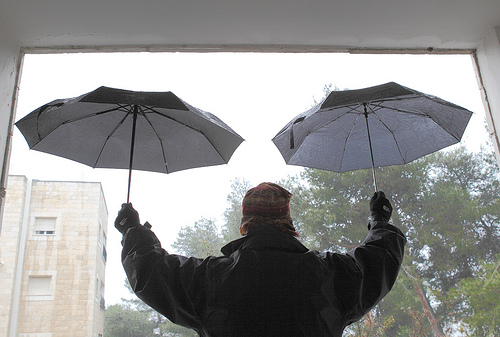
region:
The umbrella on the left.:
[20, 89, 241, 167]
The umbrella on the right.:
[274, 72, 478, 178]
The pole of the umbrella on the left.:
[124, 110, 139, 202]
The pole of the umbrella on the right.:
[362, 107, 384, 188]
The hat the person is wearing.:
[240, 182, 293, 219]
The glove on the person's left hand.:
[111, 198, 137, 230]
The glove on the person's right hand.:
[366, 190, 390, 220]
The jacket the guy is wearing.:
[127, 231, 404, 335]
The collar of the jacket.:
[215, 233, 309, 255]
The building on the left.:
[5, 170, 114, 334]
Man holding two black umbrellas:
[113, 176, 407, 335]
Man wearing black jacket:
[112, 180, 406, 335]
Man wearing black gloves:
[112, 180, 407, 335]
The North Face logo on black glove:
[117, 214, 130, 228]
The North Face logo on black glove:
[380, 200, 392, 212]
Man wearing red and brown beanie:
[112, 177, 407, 335]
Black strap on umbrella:
[285, 115, 305, 151]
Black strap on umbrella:
[32, 100, 66, 147]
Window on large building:
[34, 213, 58, 234]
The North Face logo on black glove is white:
[115, 213, 128, 227]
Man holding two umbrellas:
[12, 78, 477, 335]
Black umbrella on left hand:
[13, 86, 248, 261]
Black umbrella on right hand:
[271, 77, 480, 249]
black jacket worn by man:
[112, 223, 411, 335]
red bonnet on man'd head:
[238, 180, 296, 220]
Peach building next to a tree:
[0, 177, 112, 335]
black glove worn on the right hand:
[367, 190, 397, 228]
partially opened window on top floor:
[27, 209, 64, 238]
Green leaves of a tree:
[443, 265, 498, 330]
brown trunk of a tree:
[404, 264, 448, 335]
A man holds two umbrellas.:
[15, 82, 472, 334]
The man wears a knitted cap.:
[245, 190, 287, 215]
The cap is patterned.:
[245, 189, 286, 213]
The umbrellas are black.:
[16, 80, 473, 172]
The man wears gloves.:
[114, 202, 138, 233]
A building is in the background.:
[0, 176, 109, 335]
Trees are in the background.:
[432, 169, 492, 330]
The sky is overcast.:
[28, 55, 377, 82]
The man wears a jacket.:
[202, 257, 337, 334]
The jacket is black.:
[201, 258, 339, 335]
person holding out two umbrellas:
[20, 65, 488, 300]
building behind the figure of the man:
[11, 163, 108, 334]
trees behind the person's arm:
[302, 165, 475, 334]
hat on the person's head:
[244, 173, 290, 228]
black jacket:
[127, 225, 410, 335]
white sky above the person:
[209, 68, 280, 106]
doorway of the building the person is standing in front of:
[7, 13, 490, 291]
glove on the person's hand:
[111, 203, 142, 225]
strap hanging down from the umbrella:
[283, 103, 308, 159]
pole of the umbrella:
[117, 162, 148, 202]